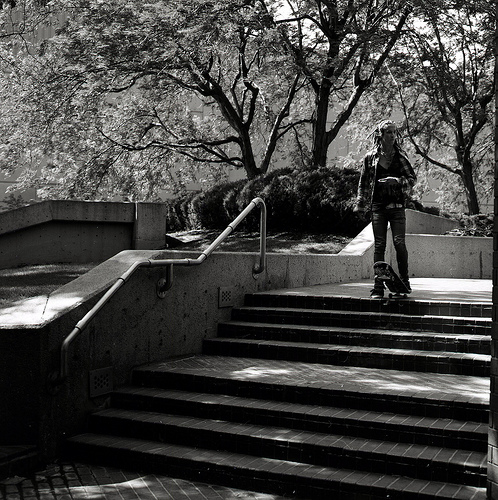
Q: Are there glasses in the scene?
A: No, there are no glasses.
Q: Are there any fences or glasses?
A: No, there are no glasses or fences.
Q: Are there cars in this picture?
A: No, there are no cars.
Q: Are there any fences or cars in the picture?
A: No, there are no cars or fences.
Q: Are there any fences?
A: No, there are no fences.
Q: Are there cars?
A: No, there are no cars.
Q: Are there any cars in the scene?
A: No, there are no cars.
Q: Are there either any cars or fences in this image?
A: No, there are no cars or fences.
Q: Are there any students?
A: No, there are no students.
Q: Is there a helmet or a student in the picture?
A: No, there are no students or helmets.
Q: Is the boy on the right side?
A: Yes, the boy is on the right of the image.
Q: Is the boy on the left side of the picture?
A: No, the boy is on the right of the image.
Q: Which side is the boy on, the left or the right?
A: The boy is on the right of the image.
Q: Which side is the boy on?
A: The boy is on the right of the image.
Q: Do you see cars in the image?
A: No, there are no cars.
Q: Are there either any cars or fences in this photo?
A: No, there are no cars or fences.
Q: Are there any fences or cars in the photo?
A: No, there are no cars or fences.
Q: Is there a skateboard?
A: Yes, there is a skateboard.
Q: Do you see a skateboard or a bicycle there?
A: Yes, there is a skateboard.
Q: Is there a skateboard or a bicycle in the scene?
A: Yes, there is a skateboard.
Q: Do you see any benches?
A: No, there are no benches.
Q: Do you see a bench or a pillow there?
A: No, there are no benches or pillows.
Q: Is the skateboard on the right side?
A: Yes, the skateboard is on the right of the image.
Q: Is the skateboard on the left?
A: No, the skateboard is on the right of the image.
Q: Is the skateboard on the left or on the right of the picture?
A: The skateboard is on the right of the image.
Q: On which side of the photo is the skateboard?
A: The skateboard is on the right of the image.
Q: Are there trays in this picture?
A: No, there are no trays.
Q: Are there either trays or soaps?
A: No, there are no trays or soaps.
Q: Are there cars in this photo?
A: No, there are no cars.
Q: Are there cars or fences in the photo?
A: No, there are no cars or fences.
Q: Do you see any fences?
A: No, there are no fences.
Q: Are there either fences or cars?
A: No, there are no fences or cars.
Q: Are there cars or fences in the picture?
A: No, there are no fences or cars.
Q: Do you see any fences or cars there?
A: No, there are no fences or cars.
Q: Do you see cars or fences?
A: No, there are no fences or cars.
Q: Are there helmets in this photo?
A: No, there are no helmets.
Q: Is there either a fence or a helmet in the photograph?
A: No, there are no helmets or fences.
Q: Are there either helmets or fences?
A: No, there are no helmets or fences.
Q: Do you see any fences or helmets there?
A: No, there are no helmets or fences.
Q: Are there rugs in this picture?
A: No, there are no rugs.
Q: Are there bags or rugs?
A: No, there are no rugs or bags.